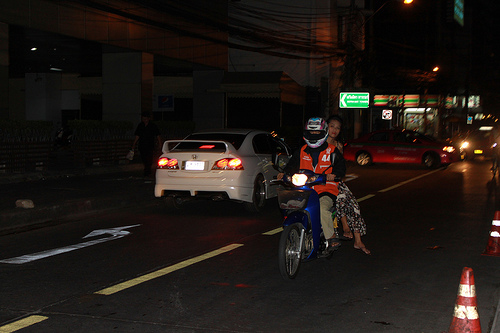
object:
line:
[260, 224, 283, 236]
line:
[93, 243, 244, 296]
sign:
[373, 93, 480, 108]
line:
[356, 194, 375, 202]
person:
[130, 104, 162, 187]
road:
[0, 145, 500, 333]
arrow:
[0, 223, 142, 265]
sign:
[403, 107, 438, 136]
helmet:
[302, 118, 329, 149]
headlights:
[447, 146, 455, 153]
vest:
[299, 144, 340, 197]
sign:
[374, 94, 421, 107]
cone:
[442, 266, 487, 332]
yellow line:
[0, 312, 50, 332]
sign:
[382, 109, 393, 120]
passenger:
[326, 116, 374, 256]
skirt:
[334, 180, 367, 236]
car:
[151, 127, 293, 209]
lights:
[228, 158, 242, 167]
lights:
[158, 157, 169, 166]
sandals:
[352, 244, 377, 257]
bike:
[267, 161, 339, 282]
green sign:
[339, 91, 369, 108]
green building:
[227, 0, 373, 162]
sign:
[453, 93, 482, 109]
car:
[344, 128, 455, 170]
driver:
[277, 117, 339, 256]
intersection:
[378, 158, 465, 194]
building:
[0, 0, 231, 184]